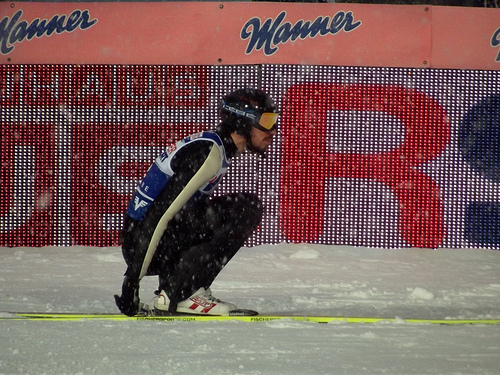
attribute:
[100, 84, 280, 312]
skier — kneeling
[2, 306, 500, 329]
skis — neon green, yellow, long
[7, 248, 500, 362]
snow — white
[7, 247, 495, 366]
ground — snow covered, white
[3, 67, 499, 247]
sign — digital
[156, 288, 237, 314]
sneakers — red, white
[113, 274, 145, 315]
gloves — black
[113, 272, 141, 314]
hands — skier's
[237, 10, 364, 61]
manner — written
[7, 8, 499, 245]
wall — orange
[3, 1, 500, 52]
logos — sponsor's, black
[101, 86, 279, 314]
man — crouched over, crouched down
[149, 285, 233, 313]
shoes — white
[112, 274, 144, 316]
glove — black, man's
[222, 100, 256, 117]
strap — white, attached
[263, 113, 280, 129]
tint — yellow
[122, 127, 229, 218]
vest — blue, white, competition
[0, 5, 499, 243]
billboard — pink, advertisement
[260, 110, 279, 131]
lens — amber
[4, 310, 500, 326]
snow skis — long jumping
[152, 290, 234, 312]
ski boot — here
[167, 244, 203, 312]
binder — here, ski jumping boot's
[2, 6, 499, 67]
banner — advertising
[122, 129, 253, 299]
suit — black, beige, ski jumper's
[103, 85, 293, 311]
position — squatting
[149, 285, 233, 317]
tennis shoes — white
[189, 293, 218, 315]
accents — red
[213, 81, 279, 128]
helmet — black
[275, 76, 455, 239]
r — large, capital, red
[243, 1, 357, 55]
word — manners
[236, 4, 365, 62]
letters — cursive, colorful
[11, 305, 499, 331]
object — long, yellow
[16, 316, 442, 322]
text — black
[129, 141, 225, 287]
sleeve — black, white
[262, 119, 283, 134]
eyes — man's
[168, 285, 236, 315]
ski boots — white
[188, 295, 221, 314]
stripes — red